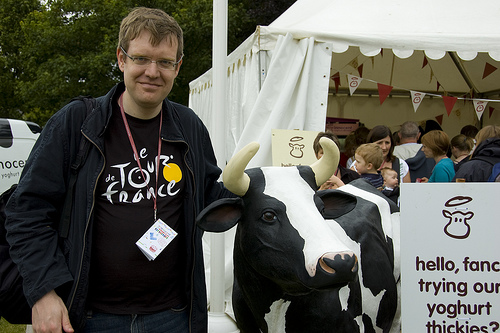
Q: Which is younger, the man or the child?
A: The child is younger than the man.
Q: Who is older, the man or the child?
A: The man is older than the child.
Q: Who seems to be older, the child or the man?
A: The man is older than the child.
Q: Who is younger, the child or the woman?
A: The child is younger than the woman.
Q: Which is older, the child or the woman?
A: The woman is older than the child.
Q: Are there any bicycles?
A: No, there are no bicycles.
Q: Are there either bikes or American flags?
A: No, there are no bikes or American flags.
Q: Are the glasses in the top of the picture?
A: Yes, the glasses are in the top of the image.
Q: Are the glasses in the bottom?
A: No, the glasses are in the top of the image.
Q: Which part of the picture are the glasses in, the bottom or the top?
A: The glasses are in the top of the image.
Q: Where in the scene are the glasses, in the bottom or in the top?
A: The glasses are in the top of the image.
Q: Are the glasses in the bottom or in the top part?
A: The glasses are in the top of the image.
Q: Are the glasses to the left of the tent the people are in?
A: Yes, the glasses are to the left of the tent.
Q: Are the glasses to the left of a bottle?
A: No, the glasses are to the left of the tent.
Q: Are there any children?
A: Yes, there is a child.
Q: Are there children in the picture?
A: Yes, there is a child.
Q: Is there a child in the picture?
A: Yes, there is a child.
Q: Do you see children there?
A: Yes, there is a child.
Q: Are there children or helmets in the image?
A: Yes, there is a child.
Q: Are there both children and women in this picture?
A: Yes, there are both a child and a woman.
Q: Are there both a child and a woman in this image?
A: Yes, there are both a child and a woman.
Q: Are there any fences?
A: No, there are no fences.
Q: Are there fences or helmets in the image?
A: No, there are no fences or helmets.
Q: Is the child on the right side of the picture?
A: Yes, the child is on the right of the image.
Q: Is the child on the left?
A: No, the child is on the right of the image.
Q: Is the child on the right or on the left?
A: The child is on the right of the image.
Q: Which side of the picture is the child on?
A: The child is on the right of the image.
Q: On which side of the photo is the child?
A: The child is on the right of the image.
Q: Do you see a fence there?
A: No, there are no fences.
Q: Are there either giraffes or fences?
A: No, there are no fences or giraffes.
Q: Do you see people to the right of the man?
A: Yes, there are people to the right of the man.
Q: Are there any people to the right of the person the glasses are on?
A: Yes, there are people to the right of the man.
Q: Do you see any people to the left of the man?
A: No, the people are to the right of the man.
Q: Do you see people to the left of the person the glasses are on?
A: No, the people are to the right of the man.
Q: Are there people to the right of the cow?
A: Yes, there are people to the right of the cow.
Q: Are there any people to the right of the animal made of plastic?
A: Yes, there are people to the right of the cow.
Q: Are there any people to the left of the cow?
A: No, the people are to the right of the cow.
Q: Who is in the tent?
A: The people are in the tent.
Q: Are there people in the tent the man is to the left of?
A: Yes, there are people in the tent.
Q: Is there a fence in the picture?
A: No, there are no fences.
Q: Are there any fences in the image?
A: No, there are no fences.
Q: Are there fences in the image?
A: No, there are no fences.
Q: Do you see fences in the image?
A: No, there are no fences.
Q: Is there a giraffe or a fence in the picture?
A: No, there are no fences or giraffes.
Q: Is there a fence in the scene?
A: No, there are no fences.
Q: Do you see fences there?
A: No, there are no fences.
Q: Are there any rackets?
A: No, there are no rackets.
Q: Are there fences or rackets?
A: No, there are no rackets or fences.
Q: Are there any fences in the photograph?
A: No, there are no fences.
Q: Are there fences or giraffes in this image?
A: No, there are no fences or giraffes.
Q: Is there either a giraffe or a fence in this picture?
A: No, there are no fences or giraffes.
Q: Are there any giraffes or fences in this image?
A: No, there are no fences or giraffes.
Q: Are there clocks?
A: No, there are no clocks.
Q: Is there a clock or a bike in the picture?
A: No, there are no clocks or bikes.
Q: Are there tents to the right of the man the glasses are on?
A: Yes, there is a tent to the right of the man.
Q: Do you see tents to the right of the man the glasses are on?
A: Yes, there is a tent to the right of the man.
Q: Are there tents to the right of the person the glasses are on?
A: Yes, there is a tent to the right of the man.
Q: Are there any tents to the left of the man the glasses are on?
A: No, the tent is to the right of the man.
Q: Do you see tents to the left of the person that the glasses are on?
A: No, the tent is to the right of the man.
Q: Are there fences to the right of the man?
A: No, there is a tent to the right of the man.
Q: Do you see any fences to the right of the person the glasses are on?
A: No, there is a tent to the right of the man.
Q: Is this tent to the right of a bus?
A: No, the tent is to the right of a man.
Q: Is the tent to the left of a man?
A: No, the tent is to the right of a man.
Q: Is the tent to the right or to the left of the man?
A: The tent is to the right of the man.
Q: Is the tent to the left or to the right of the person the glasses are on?
A: The tent is to the right of the man.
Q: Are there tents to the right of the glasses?
A: Yes, there is a tent to the right of the glasses.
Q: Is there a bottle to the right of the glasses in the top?
A: No, there is a tent to the right of the glasses.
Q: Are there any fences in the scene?
A: No, there are no fences.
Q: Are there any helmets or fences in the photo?
A: No, there are no fences or helmets.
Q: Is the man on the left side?
A: Yes, the man is on the left of the image.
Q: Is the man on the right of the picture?
A: No, the man is on the left of the image.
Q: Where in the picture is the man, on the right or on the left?
A: The man is on the left of the image.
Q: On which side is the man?
A: The man is on the left of the image.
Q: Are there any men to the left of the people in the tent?
A: Yes, there is a man to the left of the people.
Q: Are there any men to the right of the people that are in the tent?
A: No, the man is to the left of the people.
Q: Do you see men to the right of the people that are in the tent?
A: No, the man is to the left of the people.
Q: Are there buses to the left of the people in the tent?
A: No, there is a man to the left of the people.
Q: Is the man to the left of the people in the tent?
A: Yes, the man is to the left of the people.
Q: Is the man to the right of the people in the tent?
A: No, the man is to the left of the people.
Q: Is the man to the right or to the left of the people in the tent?
A: The man is to the left of the people.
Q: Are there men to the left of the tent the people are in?
A: Yes, there is a man to the left of the tent.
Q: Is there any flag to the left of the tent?
A: No, there is a man to the left of the tent.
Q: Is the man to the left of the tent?
A: Yes, the man is to the left of the tent.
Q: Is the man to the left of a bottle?
A: No, the man is to the left of the tent.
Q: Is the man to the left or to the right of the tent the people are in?
A: The man is to the left of the tent.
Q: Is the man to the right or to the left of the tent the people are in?
A: The man is to the left of the tent.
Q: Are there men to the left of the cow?
A: Yes, there is a man to the left of the cow.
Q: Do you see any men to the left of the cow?
A: Yes, there is a man to the left of the cow.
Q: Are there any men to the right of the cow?
A: No, the man is to the left of the cow.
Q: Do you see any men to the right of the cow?
A: No, the man is to the left of the cow.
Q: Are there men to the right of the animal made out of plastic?
A: No, the man is to the left of the cow.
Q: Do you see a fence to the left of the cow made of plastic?
A: No, there is a man to the left of the cow.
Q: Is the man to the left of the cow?
A: Yes, the man is to the left of the cow.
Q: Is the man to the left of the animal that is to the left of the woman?
A: Yes, the man is to the left of the cow.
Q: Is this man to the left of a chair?
A: No, the man is to the left of the cow.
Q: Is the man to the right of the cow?
A: No, the man is to the left of the cow.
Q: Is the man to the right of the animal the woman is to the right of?
A: No, the man is to the left of the cow.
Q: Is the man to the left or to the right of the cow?
A: The man is to the left of the cow.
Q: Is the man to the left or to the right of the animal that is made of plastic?
A: The man is to the left of the cow.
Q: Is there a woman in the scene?
A: Yes, there is a woman.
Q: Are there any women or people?
A: Yes, there is a woman.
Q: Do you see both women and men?
A: Yes, there are both a woman and a man.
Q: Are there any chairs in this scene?
A: No, there are no chairs.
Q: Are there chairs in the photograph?
A: No, there are no chairs.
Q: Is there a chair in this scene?
A: No, there are no chairs.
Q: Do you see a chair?
A: No, there are no chairs.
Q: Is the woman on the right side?
A: Yes, the woman is on the right of the image.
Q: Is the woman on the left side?
A: No, the woman is on the right of the image.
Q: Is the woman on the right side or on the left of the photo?
A: The woman is on the right of the image.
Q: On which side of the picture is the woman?
A: The woman is on the right of the image.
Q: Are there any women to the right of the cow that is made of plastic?
A: Yes, there is a woman to the right of the cow.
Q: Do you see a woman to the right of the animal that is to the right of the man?
A: Yes, there is a woman to the right of the cow.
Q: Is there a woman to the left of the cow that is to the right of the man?
A: No, the woman is to the right of the cow.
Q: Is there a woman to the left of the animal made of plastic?
A: No, the woman is to the right of the cow.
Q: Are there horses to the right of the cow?
A: No, there is a woman to the right of the cow.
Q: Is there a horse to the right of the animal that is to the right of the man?
A: No, there is a woman to the right of the cow.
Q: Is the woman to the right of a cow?
A: Yes, the woman is to the right of a cow.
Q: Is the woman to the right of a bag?
A: No, the woman is to the right of a cow.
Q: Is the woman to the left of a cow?
A: No, the woman is to the right of a cow.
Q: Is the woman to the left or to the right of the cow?
A: The woman is to the right of the cow.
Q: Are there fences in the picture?
A: No, there are no fences.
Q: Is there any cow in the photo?
A: Yes, there is a cow.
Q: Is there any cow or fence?
A: Yes, there is a cow.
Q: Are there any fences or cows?
A: Yes, there is a cow.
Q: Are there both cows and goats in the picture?
A: No, there is a cow but no goats.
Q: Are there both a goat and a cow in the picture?
A: No, there is a cow but no goats.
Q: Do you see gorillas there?
A: No, there are no gorillas.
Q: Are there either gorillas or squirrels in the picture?
A: No, there are no gorillas or squirrels.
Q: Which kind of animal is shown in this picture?
A: The animal is a cow.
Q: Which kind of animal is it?
A: The animal is a cow.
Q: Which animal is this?
A: That is a cow.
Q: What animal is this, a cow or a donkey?
A: That is a cow.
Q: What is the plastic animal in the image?
A: The animal is a cow.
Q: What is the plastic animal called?
A: The animal is a cow.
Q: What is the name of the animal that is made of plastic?
A: The animal is a cow.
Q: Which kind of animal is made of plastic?
A: The animal is a cow.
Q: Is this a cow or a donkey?
A: This is a cow.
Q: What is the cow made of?
A: The cow is made of plastic.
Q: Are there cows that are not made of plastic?
A: No, there is a cow but it is made of plastic.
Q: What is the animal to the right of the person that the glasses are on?
A: The animal is a cow.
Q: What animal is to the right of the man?
A: The animal is a cow.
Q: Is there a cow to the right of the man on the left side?
A: Yes, there is a cow to the right of the man.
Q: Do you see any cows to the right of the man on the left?
A: Yes, there is a cow to the right of the man.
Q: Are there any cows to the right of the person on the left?
A: Yes, there is a cow to the right of the man.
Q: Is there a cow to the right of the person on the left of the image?
A: Yes, there is a cow to the right of the man.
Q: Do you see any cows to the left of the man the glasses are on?
A: No, the cow is to the right of the man.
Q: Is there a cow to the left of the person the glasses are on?
A: No, the cow is to the right of the man.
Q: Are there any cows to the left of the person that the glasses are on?
A: No, the cow is to the right of the man.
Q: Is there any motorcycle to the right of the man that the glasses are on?
A: No, there is a cow to the right of the man.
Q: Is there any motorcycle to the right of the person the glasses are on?
A: No, there is a cow to the right of the man.